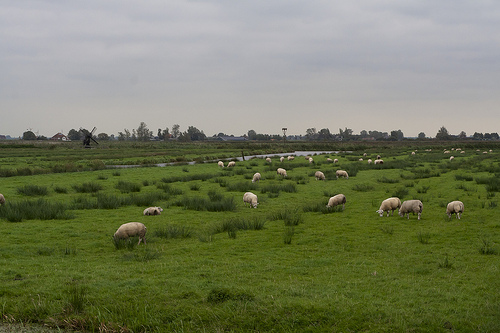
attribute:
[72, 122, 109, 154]
windmill — in distance, dark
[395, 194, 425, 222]
sheep — grey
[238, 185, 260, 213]
sheep — white, woolly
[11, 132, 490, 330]
grass — green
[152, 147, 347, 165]
water — silver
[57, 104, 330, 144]
trees — green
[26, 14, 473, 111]
sky — cloudy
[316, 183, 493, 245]
animals — tan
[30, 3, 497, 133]
sky — cloudy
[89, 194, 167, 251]
sheep — grazing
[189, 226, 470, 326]
grass — green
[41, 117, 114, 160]
windmill — brown, wooden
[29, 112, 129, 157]
farmhouse — brown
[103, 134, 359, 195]
stream — clear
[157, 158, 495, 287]
sheep — herd, grazing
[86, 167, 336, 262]
gras — tall, clumped, green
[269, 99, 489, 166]
tree — green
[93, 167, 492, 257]
sheep — bunched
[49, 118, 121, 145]
windmill — brown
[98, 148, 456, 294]
sheep — grazing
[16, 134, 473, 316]
grass — green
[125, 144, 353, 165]
stream — running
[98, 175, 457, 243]
sheep — white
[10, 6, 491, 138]
sky — grey, cloudy, gray, hazy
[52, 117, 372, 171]
trees — background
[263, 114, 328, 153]
tower — background